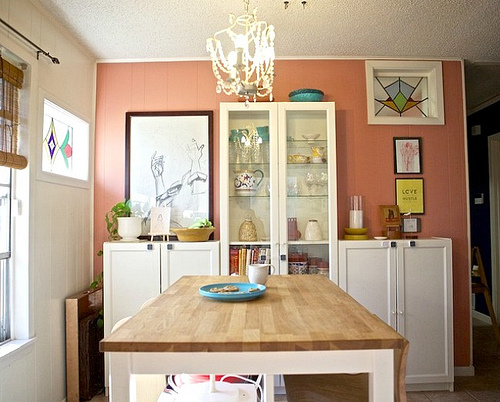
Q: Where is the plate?
A: On the table.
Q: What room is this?
A: The dining room.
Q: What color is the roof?
A: White.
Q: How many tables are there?
A: 1.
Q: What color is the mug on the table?
A: White.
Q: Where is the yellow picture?
A: On the back wall.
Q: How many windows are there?
A: 3.